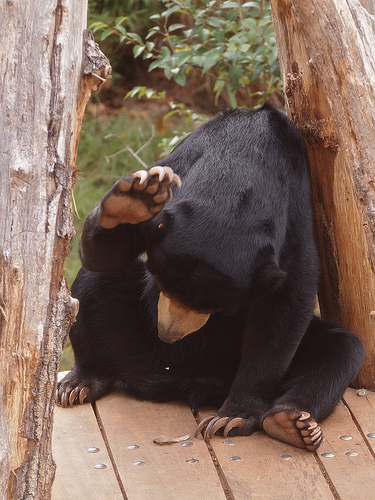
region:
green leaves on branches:
[106, 3, 272, 101]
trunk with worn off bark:
[284, 17, 372, 366]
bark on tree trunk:
[17, 281, 81, 499]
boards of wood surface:
[51, 370, 368, 496]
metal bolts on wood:
[88, 431, 373, 469]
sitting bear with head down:
[56, 103, 364, 450]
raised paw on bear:
[79, 166, 182, 272]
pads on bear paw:
[100, 180, 165, 228]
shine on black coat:
[173, 118, 282, 272]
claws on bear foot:
[195, 415, 239, 439]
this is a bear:
[88, 87, 354, 461]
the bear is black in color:
[234, 244, 297, 323]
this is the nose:
[152, 325, 188, 350]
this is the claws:
[204, 413, 223, 436]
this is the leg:
[244, 283, 296, 382]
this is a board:
[110, 421, 171, 496]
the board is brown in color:
[122, 442, 170, 491]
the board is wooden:
[95, 431, 171, 487]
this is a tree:
[158, 25, 283, 98]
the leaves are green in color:
[174, 32, 258, 72]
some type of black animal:
[43, 101, 360, 456]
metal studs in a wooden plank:
[72, 425, 156, 480]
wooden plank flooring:
[71, 425, 202, 498]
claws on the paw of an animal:
[190, 406, 256, 448]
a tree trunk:
[5, 184, 79, 467]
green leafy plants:
[151, 7, 277, 82]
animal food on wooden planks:
[145, 423, 194, 453]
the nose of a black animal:
[145, 287, 216, 355]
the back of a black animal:
[160, 100, 322, 201]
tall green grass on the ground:
[92, 111, 172, 156]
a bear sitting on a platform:
[69, 111, 361, 449]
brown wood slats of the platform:
[152, 478, 350, 499]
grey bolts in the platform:
[88, 441, 202, 486]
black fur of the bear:
[199, 132, 273, 248]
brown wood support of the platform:
[0, 67, 104, 481]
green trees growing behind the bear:
[97, 4, 160, 149]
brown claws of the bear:
[189, 415, 241, 440]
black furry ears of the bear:
[149, 201, 295, 292]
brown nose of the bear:
[152, 300, 202, 341]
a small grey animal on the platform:
[149, 430, 197, 447]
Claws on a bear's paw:
[192, 415, 242, 439]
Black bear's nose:
[157, 329, 178, 344]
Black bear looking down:
[144, 217, 288, 346]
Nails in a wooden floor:
[85, 445, 107, 472]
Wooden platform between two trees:
[47, 366, 374, 497]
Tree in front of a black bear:
[0, 0, 101, 499]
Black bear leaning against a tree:
[267, 0, 374, 390]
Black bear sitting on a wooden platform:
[62, 106, 366, 453]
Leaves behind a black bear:
[100, 5, 282, 111]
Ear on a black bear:
[260, 264, 291, 288]